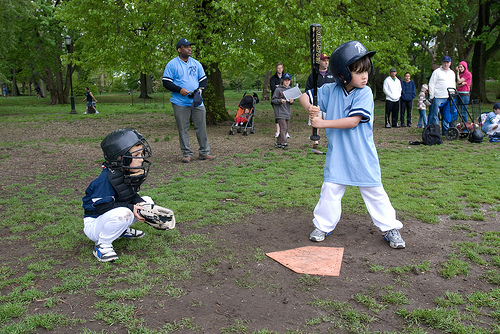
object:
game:
[4, 7, 500, 331]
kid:
[81, 127, 176, 264]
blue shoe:
[91, 240, 117, 262]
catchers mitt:
[134, 195, 175, 231]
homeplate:
[264, 244, 345, 278]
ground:
[0, 178, 500, 334]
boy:
[308, 41, 407, 249]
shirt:
[306, 82, 381, 187]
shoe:
[118, 227, 145, 241]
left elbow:
[341, 114, 361, 129]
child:
[234, 108, 250, 127]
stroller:
[229, 92, 260, 135]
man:
[161, 37, 214, 161]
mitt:
[190, 88, 203, 106]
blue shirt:
[160, 56, 208, 107]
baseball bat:
[308, 19, 322, 141]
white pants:
[309, 179, 401, 235]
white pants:
[80, 206, 133, 246]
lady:
[455, 60, 473, 123]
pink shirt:
[456, 61, 473, 92]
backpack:
[421, 122, 442, 146]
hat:
[175, 39, 197, 48]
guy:
[428, 56, 455, 134]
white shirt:
[428, 65, 455, 99]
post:
[67, 56, 77, 113]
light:
[58, 32, 86, 52]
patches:
[160, 159, 193, 186]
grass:
[187, 181, 299, 202]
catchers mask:
[99, 129, 152, 192]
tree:
[32, 11, 422, 124]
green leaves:
[100, 11, 132, 62]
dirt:
[226, 235, 289, 251]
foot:
[380, 229, 405, 249]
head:
[340, 54, 374, 89]